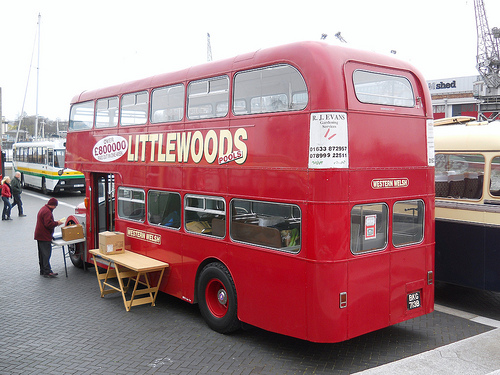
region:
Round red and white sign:
[89, 135, 131, 163]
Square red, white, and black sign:
[302, 106, 354, 174]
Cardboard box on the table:
[91, 225, 124, 254]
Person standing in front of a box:
[31, 183, 65, 284]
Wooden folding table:
[83, 241, 166, 320]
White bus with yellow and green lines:
[5, 139, 92, 197]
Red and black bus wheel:
[190, 260, 240, 339]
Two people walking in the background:
[3, 165, 28, 220]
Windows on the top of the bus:
[60, 49, 440, 131]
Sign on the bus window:
[362, 212, 378, 242]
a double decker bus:
[50, 37, 432, 351]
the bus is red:
[60, 42, 450, 347]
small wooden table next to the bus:
[85, 248, 170, 310]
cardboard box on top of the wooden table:
[93, 225, 128, 255]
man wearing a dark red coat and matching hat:
[33, 194, 64, 282]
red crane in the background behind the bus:
[468, 0, 498, 87]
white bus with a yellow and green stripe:
[21, 139, 64, 197]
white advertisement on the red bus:
[305, 112, 350, 172]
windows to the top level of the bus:
[70, 97, 302, 129]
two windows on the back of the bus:
[347, 194, 427, 258]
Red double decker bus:
[62, 41, 434, 343]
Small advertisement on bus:
[307, 112, 346, 167]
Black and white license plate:
[406, 291, 421, 310]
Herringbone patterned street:
[1, 177, 495, 372]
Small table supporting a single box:
[87, 231, 168, 311]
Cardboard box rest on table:
[97, 231, 124, 255]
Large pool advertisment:
[127, 128, 248, 162]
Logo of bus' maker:
[371, 178, 408, 189]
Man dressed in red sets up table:
[34, 198, 83, 277]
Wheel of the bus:
[195, 262, 235, 332]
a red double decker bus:
[65, 40, 435, 350]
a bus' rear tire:
[196, 263, 235, 333]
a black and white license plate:
[406, 292, 420, 309]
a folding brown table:
[87, 243, 167, 312]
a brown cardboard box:
[96, 228, 126, 255]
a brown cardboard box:
[58, 221, 83, 242]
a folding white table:
[49, 228, 86, 278]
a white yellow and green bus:
[9, 138, 86, 195]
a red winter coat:
[31, 204, 57, 241]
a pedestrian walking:
[8, 170, 27, 217]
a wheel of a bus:
[194, 265, 239, 334]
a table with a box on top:
[82, 227, 167, 317]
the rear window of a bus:
[346, 192, 430, 254]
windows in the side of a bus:
[179, 190, 306, 258]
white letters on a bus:
[125, 128, 259, 163]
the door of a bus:
[86, 172, 121, 227]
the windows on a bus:
[69, 78, 191, 128]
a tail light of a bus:
[336, 290, 353, 313]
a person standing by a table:
[24, 196, 88, 278]